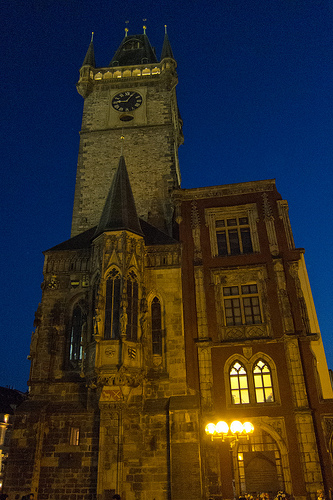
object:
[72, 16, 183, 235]
tower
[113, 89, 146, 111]
clock